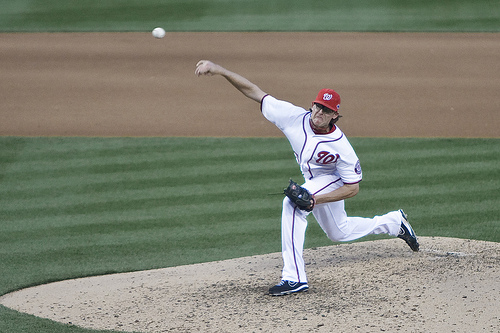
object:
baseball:
[150, 27, 166, 40]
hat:
[312, 87, 341, 114]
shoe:
[391, 207, 421, 252]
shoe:
[264, 278, 310, 296]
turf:
[19, 140, 263, 252]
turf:
[0, 2, 498, 34]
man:
[0, 235, 500, 333]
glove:
[282, 178, 314, 212]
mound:
[338, 245, 498, 328]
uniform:
[258, 95, 403, 285]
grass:
[1, 136, 498, 288]